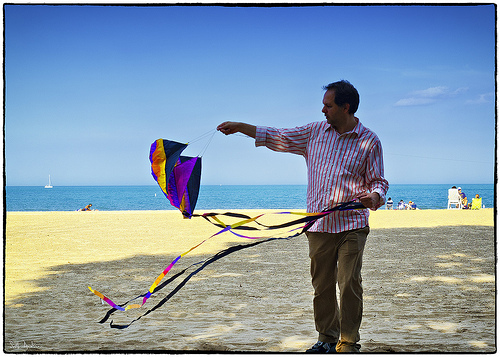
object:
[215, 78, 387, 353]
man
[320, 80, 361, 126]
head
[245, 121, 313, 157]
arm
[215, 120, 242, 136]
hand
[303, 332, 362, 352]
shoes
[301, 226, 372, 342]
pants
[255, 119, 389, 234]
shirt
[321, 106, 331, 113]
nose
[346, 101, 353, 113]
ear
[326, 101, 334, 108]
eye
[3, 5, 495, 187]
sky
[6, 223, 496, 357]
shadow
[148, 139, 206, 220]
kite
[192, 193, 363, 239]
tail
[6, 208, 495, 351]
beach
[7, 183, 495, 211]
water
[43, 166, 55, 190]
boat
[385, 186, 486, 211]
people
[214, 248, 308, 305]
sand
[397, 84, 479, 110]
cloud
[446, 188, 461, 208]
chair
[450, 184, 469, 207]
person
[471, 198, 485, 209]
chair